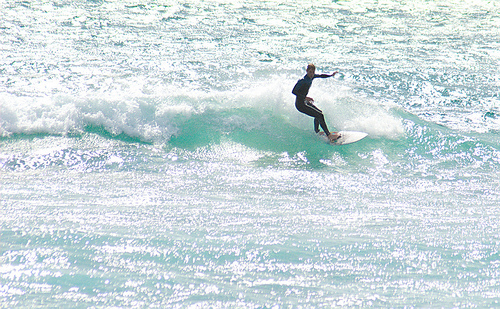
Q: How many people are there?
A: One.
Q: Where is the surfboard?
A: In the water.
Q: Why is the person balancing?
A: They are surfing.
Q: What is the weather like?
A: Sunny.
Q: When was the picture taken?
A: Daytime.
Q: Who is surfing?
A: The person.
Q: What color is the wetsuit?
A: Black.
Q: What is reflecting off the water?
A: The sun.